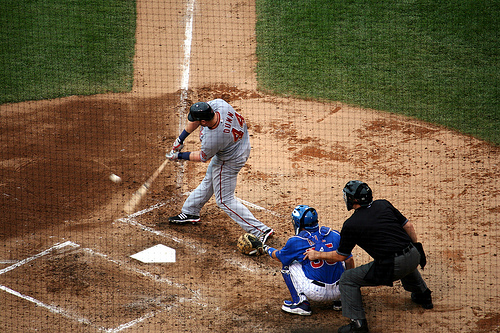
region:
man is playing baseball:
[107, 97, 270, 236]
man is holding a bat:
[112, 107, 266, 233]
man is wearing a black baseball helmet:
[181, 100, 221, 127]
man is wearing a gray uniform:
[164, 95, 267, 243]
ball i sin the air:
[108, 168, 128, 193]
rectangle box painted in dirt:
[8, 236, 175, 331]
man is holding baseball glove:
[236, 235, 278, 260]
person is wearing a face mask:
[338, 177, 380, 214]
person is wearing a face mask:
[289, 196, 311, 233]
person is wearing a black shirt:
[338, 194, 420, 267]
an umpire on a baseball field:
[300, 179, 432, 327]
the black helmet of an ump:
[342, 176, 369, 206]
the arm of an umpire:
[295, 243, 351, 264]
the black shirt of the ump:
[336, 202, 418, 252]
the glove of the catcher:
[234, 228, 261, 254]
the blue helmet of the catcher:
[290, 205, 318, 233]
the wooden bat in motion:
[117, 138, 192, 213]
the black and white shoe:
[172, 209, 202, 225]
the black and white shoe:
[255, 221, 272, 245]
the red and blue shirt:
[277, 220, 345, 277]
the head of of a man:
[173, 85, 249, 145]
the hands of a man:
[166, 118, 206, 175]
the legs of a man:
[158, 143, 305, 235]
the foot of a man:
[164, 195, 217, 242]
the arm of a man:
[153, 129, 263, 178]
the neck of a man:
[198, 107, 234, 139]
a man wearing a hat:
[181, 97, 231, 142]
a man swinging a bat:
[78, 37, 332, 257]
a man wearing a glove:
[223, 178, 368, 262]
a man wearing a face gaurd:
[322, 159, 444, 310]